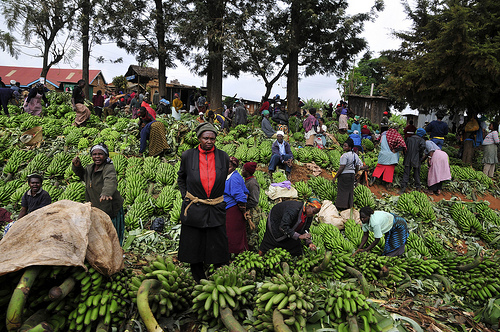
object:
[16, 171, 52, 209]
boy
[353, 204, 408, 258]
woman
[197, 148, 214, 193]
red shirt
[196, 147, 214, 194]
orange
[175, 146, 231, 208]
black jacket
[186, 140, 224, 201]
top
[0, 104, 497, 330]
ground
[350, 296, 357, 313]
banana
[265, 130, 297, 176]
man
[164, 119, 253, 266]
woman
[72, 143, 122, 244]
woman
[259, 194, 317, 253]
lady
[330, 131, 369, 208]
woman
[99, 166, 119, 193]
arm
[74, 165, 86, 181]
arm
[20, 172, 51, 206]
smiling man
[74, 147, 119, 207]
lady